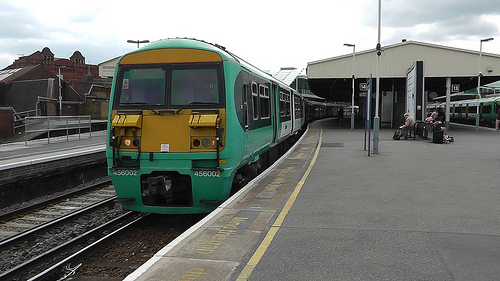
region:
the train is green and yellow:
[101, 29, 289, 233]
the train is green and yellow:
[104, 36, 200, 214]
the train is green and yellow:
[200, 38, 252, 218]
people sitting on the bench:
[372, 80, 459, 152]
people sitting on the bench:
[398, 93, 485, 190]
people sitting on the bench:
[388, 102, 452, 162]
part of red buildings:
[1, 45, 97, 87]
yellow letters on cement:
[178, 127, 318, 278]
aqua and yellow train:
[98, 31, 354, 216]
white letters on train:
[111, 163, 223, 181]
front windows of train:
[110, 59, 227, 108]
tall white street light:
[341, 39, 363, 129]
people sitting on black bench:
[386, 111, 453, 145]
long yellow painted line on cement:
[230, 122, 330, 279]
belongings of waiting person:
[429, 125, 455, 145]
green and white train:
[426, 88, 498, 122]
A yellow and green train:
[97, 39, 247, 224]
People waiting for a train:
[392, 102, 467, 159]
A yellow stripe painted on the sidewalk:
[276, 155, 329, 261]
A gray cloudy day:
[304, 6, 489, 40]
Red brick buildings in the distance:
[10, 45, 92, 123]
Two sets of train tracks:
[31, 203, 131, 274]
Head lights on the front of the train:
[108, 131, 220, 155]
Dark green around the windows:
[232, 77, 271, 130]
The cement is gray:
[348, 160, 460, 255]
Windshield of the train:
[114, 55, 222, 110]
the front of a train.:
[101, 45, 232, 225]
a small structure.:
[306, 37, 498, 133]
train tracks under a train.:
[0, 189, 185, 279]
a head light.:
[189, 122, 229, 162]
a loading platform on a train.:
[124, 125, 498, 277]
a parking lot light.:
[123, 30, 148, 58]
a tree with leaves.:
[66, 48, 83, 68]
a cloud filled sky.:
[0, 3, 499, 73]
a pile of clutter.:
[398, 54, 458, 151]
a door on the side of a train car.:
[266, 80, 283, 150]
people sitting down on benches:
[392, 109, 452, 144]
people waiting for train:
[398, 106, 458, 147]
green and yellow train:
[103, 29, 311, 225]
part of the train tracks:
[4, 190, 127, 268]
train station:
[183, 14, 498, 279]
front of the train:
[101, 35, 253, 223]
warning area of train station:
[133, 110, 326, 277]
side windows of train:
[250, 80, 282, 129]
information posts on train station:
[361, 73, 395, 157]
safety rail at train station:
[21, 112, 103, 149]